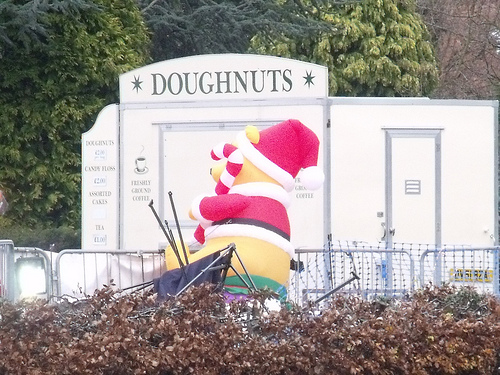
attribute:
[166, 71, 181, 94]
letter — black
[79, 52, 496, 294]
trailer — white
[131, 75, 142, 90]
star — black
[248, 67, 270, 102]
letter — black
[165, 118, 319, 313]
balloon — inflatable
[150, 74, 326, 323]
statue — blow up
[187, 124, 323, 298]
bear — blow up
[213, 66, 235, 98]
letter — black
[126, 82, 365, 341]
balloon — large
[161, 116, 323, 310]
pooh — inflatable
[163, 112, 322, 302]
bear — blow up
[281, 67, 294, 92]
letter — black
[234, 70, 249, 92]
letter — black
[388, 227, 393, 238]
handle — silver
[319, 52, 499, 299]
building — white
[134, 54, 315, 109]
letter — black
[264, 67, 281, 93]
letter — black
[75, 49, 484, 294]
building — white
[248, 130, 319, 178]
hat — red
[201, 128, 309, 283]
bear — inflatable